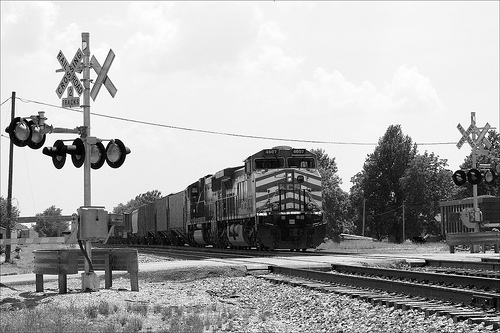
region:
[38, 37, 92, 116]
Large railroad crossing sign on a pole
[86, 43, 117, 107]
Large railroad crossing sign on a pole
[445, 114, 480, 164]
Large railroad crossing sign on a pole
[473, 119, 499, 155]
Large railroad crossing sign on a pole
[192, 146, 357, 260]
Large train engine on the train tracks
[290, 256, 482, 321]
Train tracks on the ground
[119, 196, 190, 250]
Large train carts on the tracks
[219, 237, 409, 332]
Section of the railway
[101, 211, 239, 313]
Section of the railway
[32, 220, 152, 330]
Section of the railway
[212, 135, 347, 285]
Section of the railway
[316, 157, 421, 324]
Section of the railway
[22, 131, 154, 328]
Section of the railway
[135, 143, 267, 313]
Section of the railway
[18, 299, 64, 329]
Patch of grass by the railroad tracks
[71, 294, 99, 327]
Patch of grass by the railroad tracks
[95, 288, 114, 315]
Patch of grass by the railroad tracks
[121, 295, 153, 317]
Patch of grass by the railroad tracks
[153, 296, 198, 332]
Patch of grass by the railroad tracks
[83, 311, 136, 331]
Patch of grass by the railroad tracks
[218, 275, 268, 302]
Small rocks by the railroad tracks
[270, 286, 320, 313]
Small rocks by the railroad tracks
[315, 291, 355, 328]
Small rocks by the railroad tracks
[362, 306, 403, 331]
Small rocks by the railroad tracks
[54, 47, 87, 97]
railroad crossing sign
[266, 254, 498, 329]
railroad tracks on the ground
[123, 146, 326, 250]
a cargo train on train tracks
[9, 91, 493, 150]
a long wire in the air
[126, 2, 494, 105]
very cloudy white sky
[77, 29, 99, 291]
a large metal pole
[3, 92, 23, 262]
a tall wooden pole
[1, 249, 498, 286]
a road across railroad tracks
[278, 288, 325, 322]
a pile of rocks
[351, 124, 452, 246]
a large tree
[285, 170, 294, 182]
two lights on the front of a train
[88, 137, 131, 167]
two traffic train lights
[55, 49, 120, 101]
railroad crossing X signs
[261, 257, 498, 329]
two train tracks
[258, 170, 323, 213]
stripes on the front of a train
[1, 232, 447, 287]
a concrete path crossing the tracks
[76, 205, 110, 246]
an electrical box on the train signs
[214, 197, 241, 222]
railings on the side of the train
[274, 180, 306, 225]
a black metal cattle guard on a train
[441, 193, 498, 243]
a coal transporting train car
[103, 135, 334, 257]
train on the tracks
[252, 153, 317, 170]
windshield on the front of a train